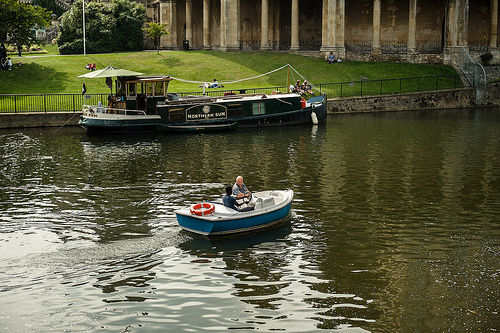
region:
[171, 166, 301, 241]
Small boat on water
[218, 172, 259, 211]
Passengers in small boat on water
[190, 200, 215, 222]
Lifesaver on small boat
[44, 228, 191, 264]
Wake in river caused by small boat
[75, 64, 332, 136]
River tour boat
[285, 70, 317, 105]
Tourists on river tour boat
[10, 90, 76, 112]
Safety rail on the sidewalk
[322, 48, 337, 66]
Person resting in the grass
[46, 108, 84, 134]
Anchor of river tour boat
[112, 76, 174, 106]
Cabin of river tour boat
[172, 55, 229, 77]
this is the grass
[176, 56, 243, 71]
the grass is green in color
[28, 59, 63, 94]
the grass is tall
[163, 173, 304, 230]
this is a boat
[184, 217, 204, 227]
the boat is blue in color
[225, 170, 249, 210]
these are some people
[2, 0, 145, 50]
these are some trees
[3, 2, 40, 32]
the leaves are green in color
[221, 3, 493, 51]
these are some buildings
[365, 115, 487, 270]
this is some water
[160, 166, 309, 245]
small motorboat on the water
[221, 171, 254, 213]
two people sitting on a boat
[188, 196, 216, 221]
orange floatation device on the back of the boat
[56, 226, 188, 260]
ripples being made by the boat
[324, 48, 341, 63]
person sitting on the grass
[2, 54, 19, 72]
person sitting in the shade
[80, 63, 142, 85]
square green umbrella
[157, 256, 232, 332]
light reflected on the water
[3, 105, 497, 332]
green body of water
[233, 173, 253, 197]
older man with white hair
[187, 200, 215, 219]
life saver ring on boat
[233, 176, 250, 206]
older white male sitting on boat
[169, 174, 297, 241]
aqua blue boat on water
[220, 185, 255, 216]
younger black male driving boat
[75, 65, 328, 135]
large boat anchored in water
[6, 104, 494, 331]
small body of green water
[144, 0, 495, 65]
old building next to pond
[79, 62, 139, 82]
green umbrella on boat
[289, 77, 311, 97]
two people lounging in grass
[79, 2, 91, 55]
flag pole on top of hill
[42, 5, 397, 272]
long and short boat by historic ruin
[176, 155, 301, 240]
two people seated on white and blue boat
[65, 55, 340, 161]
flat black boat with cabin in front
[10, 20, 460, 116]
gentle slope by river covered in grass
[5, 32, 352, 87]
a few people resting on grass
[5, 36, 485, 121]
fencing on low walls by river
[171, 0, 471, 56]
columns and pillars outside of old building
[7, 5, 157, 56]
trees and green lawn behind slope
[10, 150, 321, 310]
grey reflection of sky on rippled water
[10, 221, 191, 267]
trail of water behind moving boat